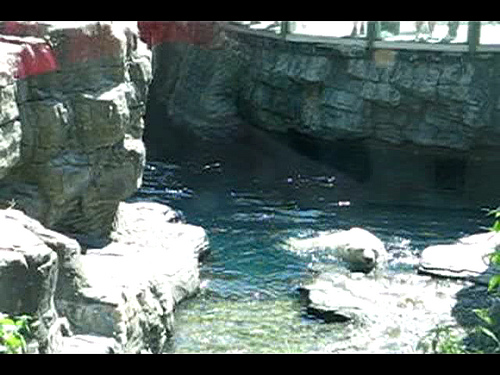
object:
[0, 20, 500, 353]
zoo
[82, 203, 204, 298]
ledge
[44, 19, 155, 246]
cliff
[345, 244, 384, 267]
bear head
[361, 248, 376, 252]
bear eyes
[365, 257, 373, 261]
bear nose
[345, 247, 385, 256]
bear ears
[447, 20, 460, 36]
legs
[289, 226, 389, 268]
bear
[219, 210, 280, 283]
blue water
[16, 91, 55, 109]
cracks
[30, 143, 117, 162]
cracks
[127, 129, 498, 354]
river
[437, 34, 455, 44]
feet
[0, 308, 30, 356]
foliage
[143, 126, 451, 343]
water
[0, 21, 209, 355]
rock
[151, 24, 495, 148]
rock